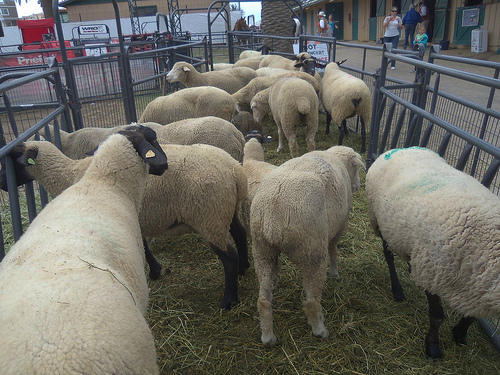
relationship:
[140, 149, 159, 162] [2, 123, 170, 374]
identification on top of sheep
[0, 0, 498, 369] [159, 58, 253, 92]
pen for sheep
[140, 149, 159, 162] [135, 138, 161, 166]
tag on top of ear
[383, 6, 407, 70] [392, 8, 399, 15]
woman has sunglasses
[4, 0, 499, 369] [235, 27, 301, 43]
pen has railing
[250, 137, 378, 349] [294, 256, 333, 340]
sheep has leg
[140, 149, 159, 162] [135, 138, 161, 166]
marker on top of ear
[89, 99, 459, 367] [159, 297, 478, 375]
ground covered in hay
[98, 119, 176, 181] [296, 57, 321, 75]
head of sheep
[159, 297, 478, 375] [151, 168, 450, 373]
hay on ground